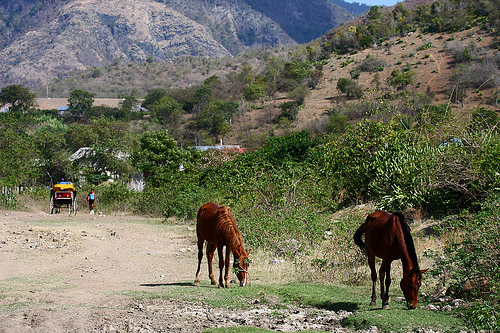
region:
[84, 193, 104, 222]
a woman standing next to a carrier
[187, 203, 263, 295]
horse with a brown mane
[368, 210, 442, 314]
horse with a black mane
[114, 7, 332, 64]
Mountains where the horses roam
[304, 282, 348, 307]
green grass for the horses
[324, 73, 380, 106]
shrubs on the side of a hill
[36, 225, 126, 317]
dirt road for riding the horses on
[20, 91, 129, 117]
roof of a building just over the hill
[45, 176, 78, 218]
stagecoach on the side of the road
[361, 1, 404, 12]
piece of blue sky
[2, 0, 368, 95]
mountain in the background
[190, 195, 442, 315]
two horses grazing in grass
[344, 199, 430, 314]
brown horse with dark mane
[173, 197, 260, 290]
light brown horse eating grass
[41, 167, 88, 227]
wagon with a yellow load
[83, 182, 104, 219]
person walking beside a wagon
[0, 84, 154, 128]
building in the distance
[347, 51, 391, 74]
bush on the hillside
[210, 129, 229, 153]
stack on a roof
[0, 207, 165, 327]
wide dirt road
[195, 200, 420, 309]
two horses graze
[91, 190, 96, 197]
a person wears a blue shirt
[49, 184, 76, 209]
a person is a cart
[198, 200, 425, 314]
two brown horses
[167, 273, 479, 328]
the grass is short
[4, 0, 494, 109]
the mountains are tall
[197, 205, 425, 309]
the horses are eating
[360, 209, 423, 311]
one horse is darker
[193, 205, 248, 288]
one horse is smaller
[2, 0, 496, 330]
the scene takes place outdoors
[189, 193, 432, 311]
Horses graze side road.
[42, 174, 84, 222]
Carriage driven man blue.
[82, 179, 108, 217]
Person blue shirt walking.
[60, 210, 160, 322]
Dirt road winds along.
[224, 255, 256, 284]
Green leaf branch head.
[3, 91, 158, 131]
Roofed building through trees.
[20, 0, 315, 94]
Sparse foliage mountain range.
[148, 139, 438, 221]
Green vegetation borders hillside.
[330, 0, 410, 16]
Slice of blue sky.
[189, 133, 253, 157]
Housing unit smoke stack.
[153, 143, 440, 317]
the horses eating grass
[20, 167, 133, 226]
a wagon and a boy in the back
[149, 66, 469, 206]
a bunch of bushes on a hill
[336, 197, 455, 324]
the darker horse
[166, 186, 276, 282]
the lighter brown horse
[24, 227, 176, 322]
the dirt on the ground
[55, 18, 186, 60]
the hill in the back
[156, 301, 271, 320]
some rocks on the ground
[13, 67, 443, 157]
what appears to be a mountainside scene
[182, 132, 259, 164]
a little home there